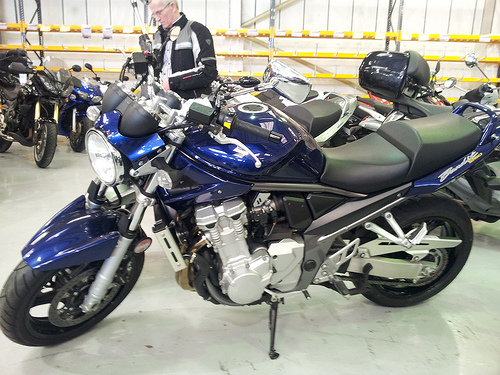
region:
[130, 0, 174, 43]
the head of a man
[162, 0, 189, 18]
the ear of a man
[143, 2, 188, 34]
the nose of a man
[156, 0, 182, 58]
the mouth of a man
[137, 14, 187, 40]
the chin of a man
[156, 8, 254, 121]
the arm of a man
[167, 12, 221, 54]
the shoulder of a man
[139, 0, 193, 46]
the hair of a man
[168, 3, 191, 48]
the neck of a man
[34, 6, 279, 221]
a man near a bike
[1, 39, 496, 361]
A motorcycle parked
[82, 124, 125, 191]
The headlight of the motorcycle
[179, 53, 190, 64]
Part of the jacket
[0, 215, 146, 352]
The front wheel of the motorcycle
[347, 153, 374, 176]
Part of the seat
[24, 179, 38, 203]
Part of the ground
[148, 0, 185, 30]
The head of the person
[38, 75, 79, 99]
The headlight of the motorcyle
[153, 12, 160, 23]
The nose of the person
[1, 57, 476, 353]
blue motorcyle in showroom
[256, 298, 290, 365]
kickstand on the bike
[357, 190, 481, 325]
rear black tire on bike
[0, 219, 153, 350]
front black tire on bike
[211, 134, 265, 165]
left brake on bike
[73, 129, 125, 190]
headlight on the blue bike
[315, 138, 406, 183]
black seat on the bike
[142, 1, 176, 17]
glasses on the man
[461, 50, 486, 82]
rearview mirror on bike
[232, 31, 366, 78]
yellow barriers behind bikes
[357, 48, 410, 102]
shiny black luggage compartment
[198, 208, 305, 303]
brand new silver motorcycle engine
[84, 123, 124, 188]
silver chrome motorcycle headlight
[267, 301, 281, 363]
small black kick stand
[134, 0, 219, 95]
man with grey hair wearing motorcycle jacket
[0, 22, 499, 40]
long yellow metal railing with silver stripes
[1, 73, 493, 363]
royal blue motorcycle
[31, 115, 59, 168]
black rubber motorcycle front tire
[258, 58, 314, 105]
back of bright chrome side view mirror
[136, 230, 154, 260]
small plastic circular reflector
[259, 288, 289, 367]
kickstand on the motorcycle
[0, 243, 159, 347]
tire on the motorcycle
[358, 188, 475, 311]
tire on the motorcycle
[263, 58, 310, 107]
side view mirror on the motorcycle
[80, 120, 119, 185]
head light on the motorcycle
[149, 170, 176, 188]
light on the motorcycle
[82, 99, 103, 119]
light on the motorcycle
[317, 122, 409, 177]
seat on the motorcycle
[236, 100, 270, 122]
on the motorcycle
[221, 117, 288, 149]
handle bar on the motorcycle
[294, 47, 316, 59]
A line of yellow.